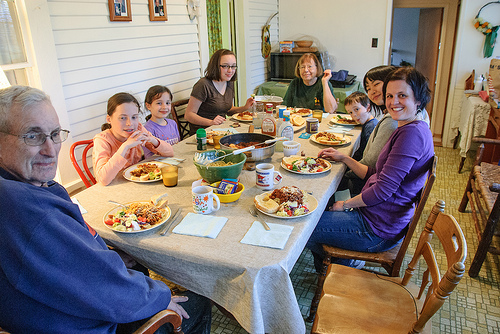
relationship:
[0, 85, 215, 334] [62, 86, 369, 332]
man sitting at table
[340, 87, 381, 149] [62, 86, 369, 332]
person sitting at table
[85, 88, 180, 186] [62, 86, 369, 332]
person sitting at table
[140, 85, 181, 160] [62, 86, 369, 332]
girl sitting at table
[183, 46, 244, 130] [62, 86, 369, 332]
person sitting at table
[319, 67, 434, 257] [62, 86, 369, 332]
person sitting at table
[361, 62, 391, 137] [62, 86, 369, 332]
person sitting at table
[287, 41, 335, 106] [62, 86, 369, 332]
person sitting at table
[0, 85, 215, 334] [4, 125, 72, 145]
man wearing glasses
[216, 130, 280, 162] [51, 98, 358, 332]
bowl on top of table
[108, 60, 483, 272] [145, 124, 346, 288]
people sitting on a table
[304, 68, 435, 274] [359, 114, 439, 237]
person wearing shirt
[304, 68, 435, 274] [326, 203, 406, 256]
person wearing blue jeans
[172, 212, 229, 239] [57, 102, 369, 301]
napkin on top of table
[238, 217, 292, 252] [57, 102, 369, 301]
napkins on top of table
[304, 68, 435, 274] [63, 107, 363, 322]
person sitting round table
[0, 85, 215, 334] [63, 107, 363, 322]
man sitting round table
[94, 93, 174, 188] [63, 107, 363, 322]
person sitting round table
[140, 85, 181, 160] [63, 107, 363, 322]
girl sitting round table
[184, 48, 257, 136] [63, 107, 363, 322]
person sitting round table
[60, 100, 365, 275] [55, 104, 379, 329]
table has tablecloth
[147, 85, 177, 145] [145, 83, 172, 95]
girl has hair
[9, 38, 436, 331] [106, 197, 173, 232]
family having dinner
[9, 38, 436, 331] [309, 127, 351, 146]
family having dinner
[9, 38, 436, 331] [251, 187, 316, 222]
family having dinner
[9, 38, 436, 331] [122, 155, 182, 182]
family having dinner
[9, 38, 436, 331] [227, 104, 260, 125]
family having dinner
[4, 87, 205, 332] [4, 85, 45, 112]
man has hair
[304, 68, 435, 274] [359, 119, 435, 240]
person wearing top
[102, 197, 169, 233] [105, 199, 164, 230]
dish full of food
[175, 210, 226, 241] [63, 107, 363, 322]
napkin over table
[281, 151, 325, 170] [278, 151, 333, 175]
food on plate